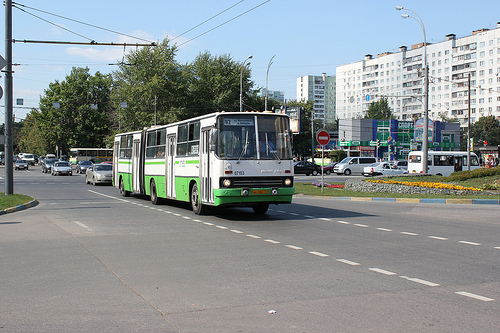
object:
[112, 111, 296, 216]
bus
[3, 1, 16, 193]
post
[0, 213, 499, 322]
road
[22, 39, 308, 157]
trees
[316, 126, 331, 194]
sign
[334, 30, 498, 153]
building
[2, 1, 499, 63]
sky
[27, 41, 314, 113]
trees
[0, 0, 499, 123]
sky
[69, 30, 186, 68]
clouds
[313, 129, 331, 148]
sign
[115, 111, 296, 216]
buses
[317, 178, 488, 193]
flowers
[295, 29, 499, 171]
buildings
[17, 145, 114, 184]
cars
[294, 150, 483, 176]
cars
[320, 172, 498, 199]
lot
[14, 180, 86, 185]
curb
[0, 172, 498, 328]
street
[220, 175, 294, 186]
headlights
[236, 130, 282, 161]
wipers